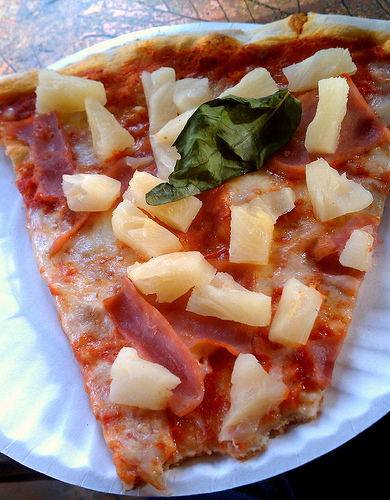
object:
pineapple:
[42, 59, 371, 430]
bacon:
[99, 275, 208, 420]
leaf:
[142, 85, 303, 207]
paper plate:
[2, 146, 388, 499]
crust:
[0, 0, 388, 82]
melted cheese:
[0, 12, 390, 492]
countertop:
[3, 10, 388, 81]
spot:
[286, 7, 313, 38]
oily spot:
[274, 222, 308, 256]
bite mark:
[122, 388, 327, 491]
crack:
[297, 9, 309, 34]